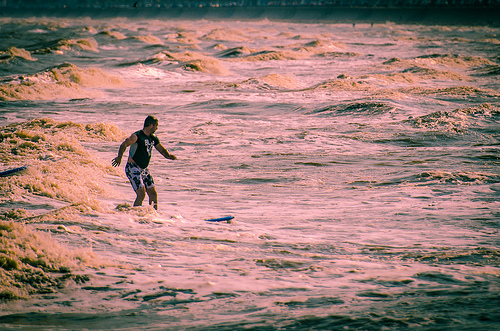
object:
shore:
[334, 311, 500, 331]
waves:
[0, 116, 129, 144]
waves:
[0, 139, 90, 163]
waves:
[34, 201, 121, 221]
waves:
[110, 203, 159, 222]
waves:
[0, 219, 132, 306]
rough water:
[0, 0, 499, 331]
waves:
[394, 99, 500, 136]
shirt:
[129, 129, 161, 169]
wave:
[140, 50, 227, 75]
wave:
[310, 71, 415, 91]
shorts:
[124, 161, 155, 192]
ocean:
[0, 16, 500, 331]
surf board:
[204, 216, 235, 223]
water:
[0, 15, 500, 331]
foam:
[0, 117, 160, 301]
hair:
[143, 115, 159, 130]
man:
[106, 112, 181, 215]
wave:
[305, 72, 362, 94]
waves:
[291, 36, 346, 55]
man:
[111, 114, 179, 210]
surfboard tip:
[228, 216, 235, 220]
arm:
[118, 133, 138, 159]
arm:
[151, 134, 170, 158]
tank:
[131, 150, 152, 169]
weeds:
[0, 115, 120, 312]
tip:
[204, 216, 235, 222]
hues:
[0, 0, 500, 331]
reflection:
[212, 147, 275, 187]